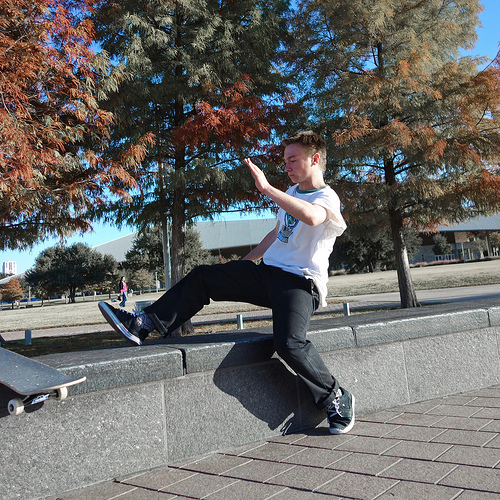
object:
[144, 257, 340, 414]
pant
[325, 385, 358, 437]
shoe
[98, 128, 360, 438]
man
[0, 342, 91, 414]
skateboard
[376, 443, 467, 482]
pavers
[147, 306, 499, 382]
sidewalk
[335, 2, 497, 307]
trees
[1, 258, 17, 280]
building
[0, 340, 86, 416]
skateboarding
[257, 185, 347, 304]
shirt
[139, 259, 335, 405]
jeans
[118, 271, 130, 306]
someone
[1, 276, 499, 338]
sidewalk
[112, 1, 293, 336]
tree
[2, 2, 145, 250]
tree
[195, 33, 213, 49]
leaves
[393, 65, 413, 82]
leaves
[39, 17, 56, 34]
leaves